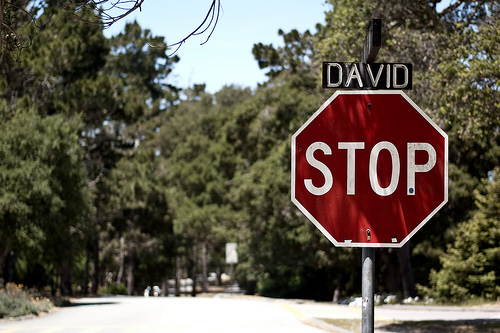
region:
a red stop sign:
[262, 53, 449, 293]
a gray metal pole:
[347, 243, 387, 330]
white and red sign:
[295, 89, 434, 264]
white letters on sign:
[300, 96, 423, 260]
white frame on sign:
[297, 106, 433, 239]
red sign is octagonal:
[301, 89, 429, 236]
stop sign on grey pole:
[302, 99, 461, 329]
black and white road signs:
[293, 38, 413, 100]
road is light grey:
[115, 266, 268, 332]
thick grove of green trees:
[150, 69, 486, 290]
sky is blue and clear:
[181, 2, 307, 73]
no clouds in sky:
[156, 0, 261, 84]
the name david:
[321, 58, 416, 88]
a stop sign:
[307, 88, 452, 255]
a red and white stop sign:
[294, 78, 454, 243]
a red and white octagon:
[288, 78, 452, 253]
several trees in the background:
[27, 10, 255, 300]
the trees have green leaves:
[169, 82, 255, 292]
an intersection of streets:
[120, 295, 359, 332]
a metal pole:
[356, 250, 383, 330]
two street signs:
[314, 15, 424, 90]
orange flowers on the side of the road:
[5, 274, 56, 314]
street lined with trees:
[13, 7, 473, 322]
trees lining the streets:
[1, 5, 489, 275]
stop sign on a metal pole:
[285, 90, 445, 330]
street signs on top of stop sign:
[306, 20, 406, 86]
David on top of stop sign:
[315, 57, 413, 89]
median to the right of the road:
[306, 310, 497, 330]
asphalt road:
[2, 255, 335, 330]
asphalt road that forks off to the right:
[0, 290, 496, 327]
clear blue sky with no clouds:
[0, 0, 492, 96]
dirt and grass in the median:
[325, 312, 493, 330]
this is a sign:
[288, 94, 455, 268]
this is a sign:
[319, 43, 416, 106]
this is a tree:
[170, 96, 261, 293]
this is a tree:
[67, 45, 153, 304]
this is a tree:
[5, 20, 82, 296]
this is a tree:
[225, 0, 346, 303]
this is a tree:
[354, 11, 498, 298]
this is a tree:
[245, 100, 330, 302]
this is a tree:
[110, 103, 237, 295]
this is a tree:
[216, 57, 301, 290]